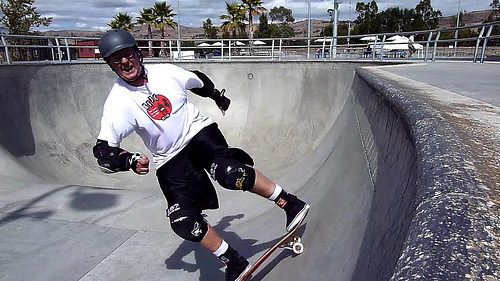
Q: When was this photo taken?
A: During the daytime.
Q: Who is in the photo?
A: A skateboarder.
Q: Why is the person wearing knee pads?
A: For protection.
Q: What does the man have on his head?
A: A helmet.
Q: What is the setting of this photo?
A: At a skatepark.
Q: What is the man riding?
A: A skateboard.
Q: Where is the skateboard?
A: Under the man's feet.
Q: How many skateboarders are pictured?
A: One.